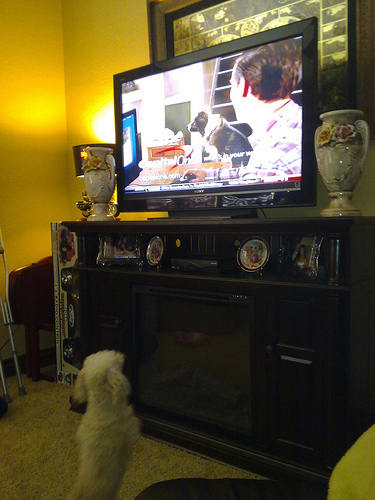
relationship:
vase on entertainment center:
[75, 142, 122, 223] [57, 216, 374, 497]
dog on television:
[191, 109, 247, 157] [103, 21, 328, 208]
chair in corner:
[9, 243, 71, 382] [39, 37, 101, 301]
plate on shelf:
[231, 235, 268, 278] [223, 226, 279, 280]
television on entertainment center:
[103, 21, 328, 208] [57, 216, 374, 497]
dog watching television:
[59, 336, 161, 497] [103, 21, 328, 208]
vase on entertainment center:
[303, 101, 372, 218] [57, 216, 374, 497]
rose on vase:
[329, 117, 359, 146] [303, 101, 372, 218]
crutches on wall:
[0, 229, 36, 411] [1, 117, 61, 252]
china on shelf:
[143, 234, 164, 271] [139, 227, 169, 278]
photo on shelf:
[105, 231, 147, 263] [85, 227, 155, 277]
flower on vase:
[78, 147, 110, 176] [75, 142, 122, 223]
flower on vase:
[314, 124, 336, 151] [303, 101, 372, 218]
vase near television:
[75, 142, 122, 223] [103, 21, 328, 208]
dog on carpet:
[59, 336, 161, 497] [11, 414, 64, 470]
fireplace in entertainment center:
[131, 286, 267, 441] [57, 216, 374, 497]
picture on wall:
[144, 3, 373, 106] [1, 117, 61, 252]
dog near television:
[59, 336, 161, 497] [103, 21, 328, 208]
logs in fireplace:
[148, 351, 250, 409] [131, 286, 267, 441]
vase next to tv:
[303, 101, 372, 218] [103, 21, 328, 208]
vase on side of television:
[75, 142, 122, 223] [103, 21, 328, 208]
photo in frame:
[105, 231, 147, 263] [280, 230, 329, 279]